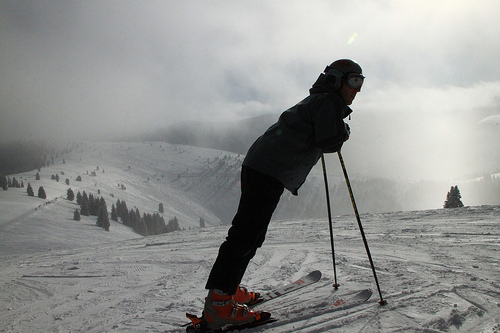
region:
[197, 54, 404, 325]
skier leaning on poles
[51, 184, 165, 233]
pine trees on slope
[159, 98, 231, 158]
mist over mountain top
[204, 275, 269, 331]
orange boots on skis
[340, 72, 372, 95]
goggles on skier's face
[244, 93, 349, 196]
winter coat on skier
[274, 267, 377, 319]
two skis on snow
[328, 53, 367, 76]
helmet on skier's head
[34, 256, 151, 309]
ski marks on snow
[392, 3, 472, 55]
sunlight in daytime sky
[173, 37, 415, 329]
skier standing in the snow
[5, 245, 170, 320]
white snow on the ground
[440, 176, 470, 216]
pine trees in the background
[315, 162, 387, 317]
ski poles used by skier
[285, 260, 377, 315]
front of two skis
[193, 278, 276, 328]
orange boots on a skier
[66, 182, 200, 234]
row of trees on snowy hill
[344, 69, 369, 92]
safety goggles on a skier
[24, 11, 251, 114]
cloudy sky in the distance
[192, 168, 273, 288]
balck ski pants on skier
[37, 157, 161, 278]
the snow is white and clear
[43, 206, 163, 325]
the snow is white and clear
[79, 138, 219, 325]
the snow is white and clear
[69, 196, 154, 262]
the snow is white and clear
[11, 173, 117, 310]
the snow is white and clear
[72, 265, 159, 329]
white snow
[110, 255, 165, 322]
white snow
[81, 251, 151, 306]
white snow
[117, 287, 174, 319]
white snow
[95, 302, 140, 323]
white snow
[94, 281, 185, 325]
white snow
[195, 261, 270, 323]
Man wearing orange ski boots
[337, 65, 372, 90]
Man wearing ski googles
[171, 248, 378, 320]
Man standing on skis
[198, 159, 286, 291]
Man wearing black snow pants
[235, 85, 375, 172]
Man wearing a black jacket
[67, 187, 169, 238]
Trees on a snowy mountain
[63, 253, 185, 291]
Ski tracks on the ground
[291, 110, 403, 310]
Man leaning on ski poles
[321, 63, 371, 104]
Man looking straight ahead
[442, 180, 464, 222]
Tree standing alone